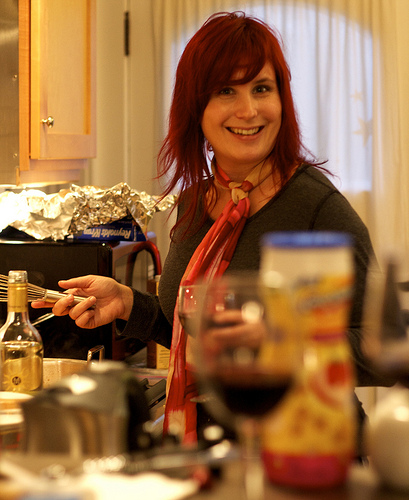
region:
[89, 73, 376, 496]
a woman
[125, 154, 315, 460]
a woman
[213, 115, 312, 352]
a woman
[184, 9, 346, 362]
a woman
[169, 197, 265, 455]
a woman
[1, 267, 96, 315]
stainless steel wire whisk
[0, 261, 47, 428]
extra virgin olive oil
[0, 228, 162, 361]
red and black microwave oven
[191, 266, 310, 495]
wine glass of red wine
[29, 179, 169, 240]
crumpled up reynolds wrap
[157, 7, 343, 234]
woman who is happy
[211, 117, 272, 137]
pretty straight white teeth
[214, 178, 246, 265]
brightly colored neck scarf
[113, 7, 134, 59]
black door hinge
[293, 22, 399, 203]
sunlight filtering through curtain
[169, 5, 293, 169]
the head of a woman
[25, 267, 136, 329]
the hand of a woman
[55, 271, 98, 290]
the thumb of a woman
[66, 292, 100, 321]
the finger of a woman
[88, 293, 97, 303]
the finger nail of a woman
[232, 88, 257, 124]
the nose of a woman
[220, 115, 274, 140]
the mouth of a woman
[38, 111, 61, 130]
a metal handle on the cabinet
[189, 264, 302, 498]
a glass of wine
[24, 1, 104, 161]
a cabinet on the wall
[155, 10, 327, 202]
a smiling woman with modern red hair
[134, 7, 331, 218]
woman with grotesque red hair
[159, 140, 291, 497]
scarf around woman's neck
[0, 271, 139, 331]
whisk in a right hand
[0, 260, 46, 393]
a bottle of olive oil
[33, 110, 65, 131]
a handle on a cupboard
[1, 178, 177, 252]
crumpled aluminum foil on foil box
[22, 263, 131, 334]
hand without fingernail polish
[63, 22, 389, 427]
woman wearing a green top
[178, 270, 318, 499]
glass of wine in the foreground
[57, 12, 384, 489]
woman with auburn hair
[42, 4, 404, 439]
woman with auburn hair holding an egg whisk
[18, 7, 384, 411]
woman with auburn hair wearing a dark shirt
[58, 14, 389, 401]
woman with auburn hair wearing a colorful scarf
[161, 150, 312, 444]
womans colorful scarf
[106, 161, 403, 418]
womans dark shirt, possibly turned inside out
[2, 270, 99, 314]
egg whisk in womans hand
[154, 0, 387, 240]
white curtain panel behind woman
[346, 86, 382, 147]
stars woven into the white curtain panel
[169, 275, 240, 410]
blurred out wine glass in the womans hand